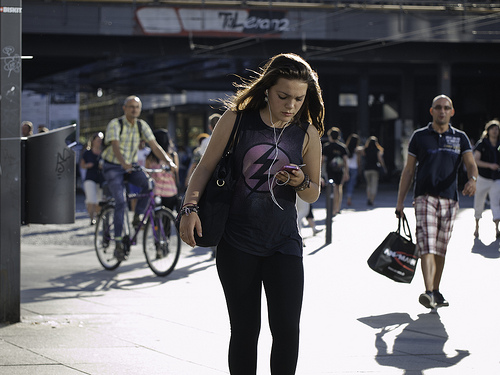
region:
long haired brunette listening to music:
[177, 44, 322, 373]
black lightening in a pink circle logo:
[242, 142, 287, 193]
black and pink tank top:
[229, 112, 306, 257]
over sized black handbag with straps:
[180, 102, 241, 239]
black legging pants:
[210, 244, 312, 371]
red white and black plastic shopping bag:
[368, 205, 414, 281]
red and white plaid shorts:
[414, 197, 454, 258]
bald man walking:
[394, 89, 474, 304]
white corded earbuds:
[261, 82, 309, 212]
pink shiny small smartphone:
[277, 159, 299, 183]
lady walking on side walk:
[149, 43, 376, 373]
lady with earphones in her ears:
[146, 37, 382, 374]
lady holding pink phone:
[125, 53, 357, 245]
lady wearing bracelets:
[174, 190, 209, 235]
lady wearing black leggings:
[170, 46, 369, 373]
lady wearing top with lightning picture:
[231, 52, 350, 294]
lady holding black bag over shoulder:
[156, 92, 256, 257]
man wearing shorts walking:
[365, 70, 490, 325]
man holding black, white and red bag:
[356, 197, 463, 317]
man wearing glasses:
[409, 87, 499, 139]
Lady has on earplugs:
[256, 75, 326, 153]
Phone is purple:
[281, 161, 298, 203]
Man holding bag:
[351, 187, 441, 305]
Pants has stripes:
[408, 198, 473, 271]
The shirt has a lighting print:
[242, 136, 301, 219]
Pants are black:
[206, 242, 359, 370]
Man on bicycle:
[89, 94, 192, 297]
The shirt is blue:
[397, 122, 479, 222]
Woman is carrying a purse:
[194, 64, 331, 250]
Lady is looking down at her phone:
[241, 55, 355, 177]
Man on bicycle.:
[87, 79, 179, 275]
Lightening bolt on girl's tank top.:
[245, 136, 277, 199]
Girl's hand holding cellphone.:
[277, 158, 306, 187]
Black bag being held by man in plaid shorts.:
[359, 208, 420, 289]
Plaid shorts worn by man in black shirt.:
[414, 198, 455, 258]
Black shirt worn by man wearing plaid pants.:
[411, 125, 477, 198]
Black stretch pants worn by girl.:
[213, 251, 318, 373]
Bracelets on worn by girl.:
[175, 196, 202, 218]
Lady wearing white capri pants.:
[476, 113, 499, 225]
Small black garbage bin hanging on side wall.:
[22, 123, 84, 230]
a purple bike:
[88, 178, 180, 276]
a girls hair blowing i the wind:
[229, 48, 332, 134]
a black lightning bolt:
[244, 133, 290, 204]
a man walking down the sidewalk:
[395, 80, 476, 346]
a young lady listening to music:
[238, 45, 325, 136]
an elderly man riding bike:
[83, 88, 185, 275]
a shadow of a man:
[369, 294, 472, 374]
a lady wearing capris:
[474, 113, 498, 254]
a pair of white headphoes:
[257, 83, 291, 208]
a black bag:
[372, 205, 424, 295]